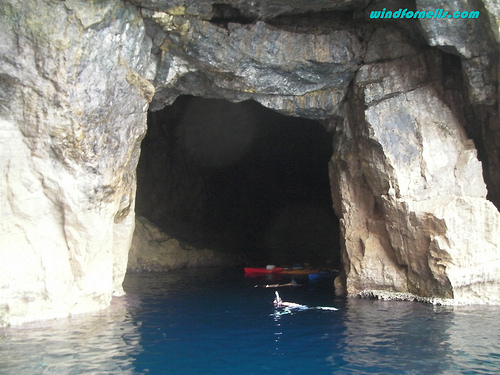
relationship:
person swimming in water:
[264, 291, 342, 318] [195, 283, 398, 349]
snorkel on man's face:
[270, 287, 283, 304] [269, 290, 288, 314]